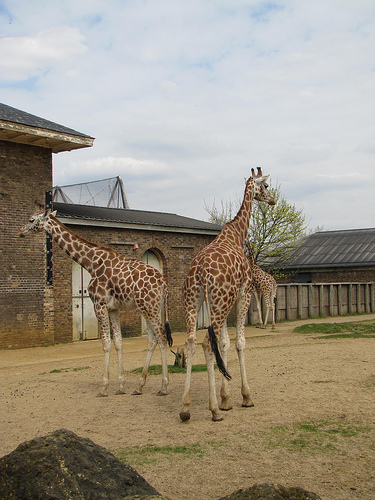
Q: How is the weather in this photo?
A: It is cloudy.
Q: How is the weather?
A: It is cloudy.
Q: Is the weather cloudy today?
A: Yes, it is cloudy.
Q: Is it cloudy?
A: Yes, it is cloudy.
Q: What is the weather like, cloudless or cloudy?
A: It is cloudy.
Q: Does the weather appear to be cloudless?
A: No, it is cloudy.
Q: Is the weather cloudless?
A: No, it is cloudy.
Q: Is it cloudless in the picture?
A: No, it is cloudy.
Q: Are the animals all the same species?
A: Yes, all the animals are giraffes.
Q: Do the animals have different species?
A: No, all the animals are giraffes.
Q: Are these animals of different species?
A: No, all the animals are giraffes.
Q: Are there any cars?
A: No, there are no cars.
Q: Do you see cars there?
A: No, there are no cars.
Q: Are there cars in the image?
A: No, there are no cars.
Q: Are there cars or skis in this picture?
A: No, there are no cars or skis.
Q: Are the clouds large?
A: Yes, the clouds are large.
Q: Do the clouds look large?
A: Yes, the clouds are large.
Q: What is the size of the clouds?
A: The clouds are large.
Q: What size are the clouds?
A: The clouds are large.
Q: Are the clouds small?
A: No, the clouds are large.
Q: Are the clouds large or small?
A: The clouds are large.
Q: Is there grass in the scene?
A: Yes, there is grass.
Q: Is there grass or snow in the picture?
A: Yes, there is grass.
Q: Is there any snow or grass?
A: Yes, there is grass.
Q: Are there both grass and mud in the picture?
A: No, there is grass but no mud.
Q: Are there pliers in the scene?
A: No, there are no pliers.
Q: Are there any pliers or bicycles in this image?
A: No, there are no pliers or bicycles.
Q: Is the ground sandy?
A: Yes, the ground is sandy.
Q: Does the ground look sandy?
A: Yes, the ground is sandy.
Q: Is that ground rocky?
A: No, the ground is sandy.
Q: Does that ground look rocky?
A: No, the ground is sandy.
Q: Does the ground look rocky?
A: No, the ground is sandy.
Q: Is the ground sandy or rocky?
A: The ground is sandy.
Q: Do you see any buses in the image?
A: No, there are no buses.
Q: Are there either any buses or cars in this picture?
A: No, there are no buses or cars.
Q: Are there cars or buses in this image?
A: No, there are no buses or cars.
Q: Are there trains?
A: No, there are no trains.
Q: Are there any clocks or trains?
A: No, there are no trains or clocks.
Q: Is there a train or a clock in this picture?
A: No, there are no trains or clocks.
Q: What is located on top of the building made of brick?
A: The roof is on top of the building.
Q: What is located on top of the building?
A: The roof is on top of the building.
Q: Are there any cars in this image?
A: No, there are no cars.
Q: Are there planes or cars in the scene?
A: No, there are no cars or planes.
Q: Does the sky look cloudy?
A: Yes, the sky is cloudy.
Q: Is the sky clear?
A: No, the sky is cloudy.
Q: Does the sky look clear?
A: No, the sky is cloudy.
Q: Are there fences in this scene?
A: Yes, there is a fence.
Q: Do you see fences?
A: Yes, there is a fence.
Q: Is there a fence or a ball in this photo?
A: Yes, there is a fence.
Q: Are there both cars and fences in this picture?
A: No, there is a fence but no cars.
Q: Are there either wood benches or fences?
A: Yes, there is a wood fence.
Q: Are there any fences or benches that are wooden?
A: Yes, the fence is wooden.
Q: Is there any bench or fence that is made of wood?
A: Yes, the fence is made of wood.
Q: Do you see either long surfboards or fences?
A: Yes, there is a long fence.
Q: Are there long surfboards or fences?
A: Yes, there is a long fence.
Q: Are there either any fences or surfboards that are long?
A: Yes, the fence is long.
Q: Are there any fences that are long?
A: Yes, there is a long fence.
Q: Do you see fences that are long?
A: Yes, there is a fence that is long.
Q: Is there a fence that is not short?
A: Yes, there is a long fence.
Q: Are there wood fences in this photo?
A: Yes, there is a wood fence.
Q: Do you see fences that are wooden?
A: Yes, there is a fence that is wooden.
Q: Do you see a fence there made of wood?
A: Yes, there is a fence that is made of wood.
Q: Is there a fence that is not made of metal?
A: Yes, there is a fence that is made of wood.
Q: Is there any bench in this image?
A: No, there are no benches.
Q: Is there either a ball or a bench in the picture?
A: No, there are no benches or balls.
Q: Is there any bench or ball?
A: No, there are no benches or balls.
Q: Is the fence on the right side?
A: Yes, the fence is on the right of the image.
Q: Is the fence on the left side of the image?
A: No, the fence is on the right of the image.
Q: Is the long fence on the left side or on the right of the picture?
A: The fence is on the right of the image.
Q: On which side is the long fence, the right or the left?
A: The fence is on the right of the image.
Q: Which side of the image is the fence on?
A: The fence is on the right of the image.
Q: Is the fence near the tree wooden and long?
A: Yes, the fence is wooden and long.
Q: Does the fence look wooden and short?
A: No, the fence is wooden but long.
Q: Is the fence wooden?
A: Yes, the fence is wooden.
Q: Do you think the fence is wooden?
A: Yes, the fence is wooden.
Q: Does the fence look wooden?
A: Yes, the fence is wooden.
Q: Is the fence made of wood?
A: Yes, the fence is made of wood.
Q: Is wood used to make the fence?
A: Yes, the fence is made of wood.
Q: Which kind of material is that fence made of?
A: The fence is made of wood.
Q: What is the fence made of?
A: The fence is made of wood.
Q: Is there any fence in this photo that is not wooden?
A: No, there is a fence but it is wooden.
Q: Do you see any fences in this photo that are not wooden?
A: No, there is a fence but it is wooden.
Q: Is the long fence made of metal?
A: No, the fence is made of wood.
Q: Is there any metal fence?
A: No, there is a fence but it is made of wood.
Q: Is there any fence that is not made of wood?
A: No, there is a fence but it is made of wood.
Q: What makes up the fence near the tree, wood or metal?
A: The fence is made of wood.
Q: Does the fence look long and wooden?
A: Yes, the fence is long and wooden.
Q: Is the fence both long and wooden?
A: Yes, the fence is long and wooden.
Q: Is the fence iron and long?
A: No, the fence is long but wooden.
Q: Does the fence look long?
A: Yes, the fence is long.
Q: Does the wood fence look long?
A: Yes, the fence is long.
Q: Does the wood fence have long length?
A: Yes, the fence is long.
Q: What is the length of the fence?
A: The fence is long.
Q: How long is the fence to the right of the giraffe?
A: The fence is long.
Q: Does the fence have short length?
A: No, the fence is long.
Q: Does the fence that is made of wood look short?
A: No, the fence is long.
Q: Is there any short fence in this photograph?
A: No, there is a fence but it is long.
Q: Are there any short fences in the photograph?
A: No, there is a fence but it is long.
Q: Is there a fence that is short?
A: No, there is a fence but it is long.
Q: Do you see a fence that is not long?
A: No, there is a fence but it is long.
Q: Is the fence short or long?
A: The fence is long.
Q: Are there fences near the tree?
A: Yes, there is a fence near the tree.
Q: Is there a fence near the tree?
A: Yes, there is a fence near the tree.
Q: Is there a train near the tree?
A: No, there is a fence near the tree.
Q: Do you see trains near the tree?
A: No, there is a fence near the tree.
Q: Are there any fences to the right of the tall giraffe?
A: Yes, there is a fence to the right of the giraffe.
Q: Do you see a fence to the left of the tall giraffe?
A: No, the fence is to the right of the giraffe.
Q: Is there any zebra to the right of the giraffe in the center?
A: No, there is a fence to the right of the giraffe.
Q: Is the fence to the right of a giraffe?
A: Yes, the fence is to the right of a giraffe.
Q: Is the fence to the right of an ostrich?
A: No, the fence is to the right of a giraffe.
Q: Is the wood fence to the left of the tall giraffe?
A: No, the fence is to the right of the giraffe.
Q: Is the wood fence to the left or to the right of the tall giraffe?
A: The fence is to the right of the giraffe.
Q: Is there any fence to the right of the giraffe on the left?
A: Yes, there is a fence to the right of the giraffe.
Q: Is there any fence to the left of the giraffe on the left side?
A: No, the fence is to the right of the giraffe.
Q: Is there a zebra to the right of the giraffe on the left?
A: No, there is a fence to the right of the giraffe.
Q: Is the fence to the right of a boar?
A: No, the fence is to the right of the giraffe.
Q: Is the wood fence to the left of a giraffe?
A: No, the fence is to the right of a giraffe.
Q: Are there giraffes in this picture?
A: Yes, there is a giraffe.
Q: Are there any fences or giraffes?
A: Yes, there is a giraffe.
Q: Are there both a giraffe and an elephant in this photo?
A: No, there is a giraffe but no elephants.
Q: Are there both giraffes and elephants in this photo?
A: No, there is a giraffe but no elephants.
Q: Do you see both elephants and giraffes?
A: No, there is a giraffe but no elephants.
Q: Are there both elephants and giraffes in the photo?
A: No, there is a giraffe but no elephants.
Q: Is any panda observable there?
A: No, there are no pandas.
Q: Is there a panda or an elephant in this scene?
A: No, there are no pandas or elephants.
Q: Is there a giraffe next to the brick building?
A: Yes, there is a giraffe next to the building.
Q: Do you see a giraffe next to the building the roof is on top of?
A: Yes, there is a giraffe next to the building.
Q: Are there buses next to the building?
A: No, there is a giraffe next to the building.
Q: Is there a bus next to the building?
A: No, there is a giraffe next to the building.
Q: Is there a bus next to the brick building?
A: No, there is a giraffe next to the building.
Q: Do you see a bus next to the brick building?
A: No, there is a giraffe next to the building.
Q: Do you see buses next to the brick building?
A: No, there is a giraffe next to the building.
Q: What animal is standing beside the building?
A: The giraffe is standing beside the building.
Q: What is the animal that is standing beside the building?
A: The animal is a giraffe.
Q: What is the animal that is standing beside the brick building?
A: The animal is a giraffe.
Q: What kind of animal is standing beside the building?
A: The animal is a giraffe.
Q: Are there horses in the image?
A: No, there are no horses.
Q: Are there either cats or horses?
A: No, there are no horses or cats.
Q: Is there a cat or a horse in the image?
A: No, there are no horses or cats.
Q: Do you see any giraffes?
A: Yes, there is a giraffe.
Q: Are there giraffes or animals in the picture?
A: Yes, there is a giraffe.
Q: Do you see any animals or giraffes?
A: Yes, there is a giraffe.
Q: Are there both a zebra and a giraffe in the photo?
A: No, there is a giraffe but no zebras.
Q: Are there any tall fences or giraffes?
A: Yes, there is a tall giraffe.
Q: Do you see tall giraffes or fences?
A: Yes, there is a tall giraffe.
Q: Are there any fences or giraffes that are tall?
A: Yes, the giraffe is tall.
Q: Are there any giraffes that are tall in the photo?
A: Yes, there is a tall giraffe.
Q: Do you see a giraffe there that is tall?
A: Yes, there is a giraffe that is tall.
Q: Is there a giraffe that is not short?
A: Yes, there is a tall giraffe.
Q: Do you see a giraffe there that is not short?
A: Yes, there is a tall giraffe.